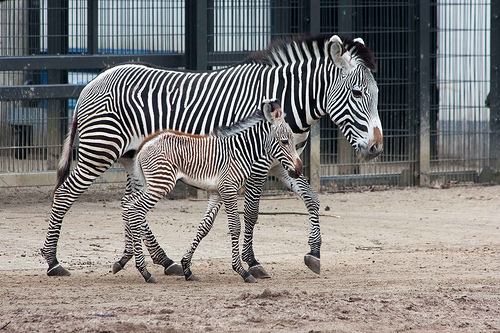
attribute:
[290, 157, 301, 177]
nose — brown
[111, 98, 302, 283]
zebra — baby, small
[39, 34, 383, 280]
zebra — adult, black, white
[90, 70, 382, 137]
zebra — black, white, striped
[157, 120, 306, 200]
zebra — striped, white, black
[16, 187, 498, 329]
floor — soil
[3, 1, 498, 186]
cage — metal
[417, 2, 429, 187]
posts — thin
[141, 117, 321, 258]
zebra — baby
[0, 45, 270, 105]
bars — horizontal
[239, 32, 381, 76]
mane — white, black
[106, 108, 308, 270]
zebra — baby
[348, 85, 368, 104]
eye — almond-shaped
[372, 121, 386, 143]
marking — brown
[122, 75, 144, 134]
stripes — black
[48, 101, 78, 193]
tail — black, white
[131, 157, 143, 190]
tail — black, white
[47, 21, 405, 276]
stripes — white, black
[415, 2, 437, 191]
post — wooden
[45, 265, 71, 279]
hoofs — black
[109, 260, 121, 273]
hoofs — black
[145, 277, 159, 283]
hoofs — black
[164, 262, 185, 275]
hoofs — black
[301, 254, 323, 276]
hoofs — black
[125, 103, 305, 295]
zebra — black, white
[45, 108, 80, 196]
tail — short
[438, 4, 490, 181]
fencing — WIRE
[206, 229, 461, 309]
floor — brown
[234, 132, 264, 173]
stripes — black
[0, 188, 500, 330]
ground — disturbed, sandy